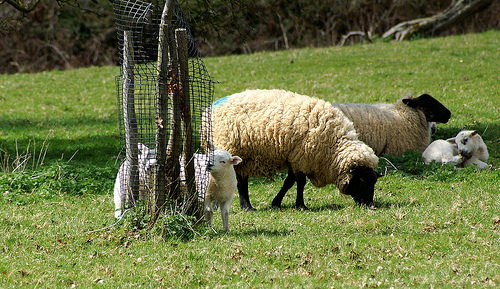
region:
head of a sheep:
[336, 128, 393, 212]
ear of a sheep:
[346, 143, 398, 181]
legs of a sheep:
[232, 172, 319, 207]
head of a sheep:
[193, 143, 243, 173]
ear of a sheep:
[232, 143, 249, 175]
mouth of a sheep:
[346, 182, 390, 220]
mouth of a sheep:
[192, 161, 227, 178]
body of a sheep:
[190, 73, 352, 184]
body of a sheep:
[336, 89, 431, 147]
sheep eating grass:
[206, 63, 438, 199]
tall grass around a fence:
[120, 190, 202, 233]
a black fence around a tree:
[109, 11, 225, 234]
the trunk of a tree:
[360, 10, 497, 34]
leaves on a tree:
[26, 0, 441, 56]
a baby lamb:
[199, 143, 252, 244]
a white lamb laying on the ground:
[418, 117, 485, 158]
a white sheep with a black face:
[224, 97, 393, 202]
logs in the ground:
[148, 16, 200, 201]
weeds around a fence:
[119, 198, 201, 233]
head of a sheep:
[335, 143, 403, 211]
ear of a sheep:
[363, 158, 390, 188]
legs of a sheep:
[230, 159, 321, 213]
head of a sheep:
[412, 79, 456, 127]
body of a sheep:
[195, 82, 330, 183]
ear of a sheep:
[403, 79, 427, 111]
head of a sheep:
[189, 138, 251, 183]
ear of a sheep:
[226, 153, 243, 164]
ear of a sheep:
[193, 132, 220, 152]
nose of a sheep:
[199, 151, 219, 176]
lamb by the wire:
[192, 137, 245, 231]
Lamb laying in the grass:
[412, 122, 487, 180]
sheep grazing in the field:
[220, 84, 377, 216]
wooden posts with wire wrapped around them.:
[128, 22, 205, 223]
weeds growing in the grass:
[9, 126, 74, 201]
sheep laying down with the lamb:
[373, 88, 496, 190]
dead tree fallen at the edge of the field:
[376, 6, 491, 36]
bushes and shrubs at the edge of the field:
[207, 7, 307, 49]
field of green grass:
[309, 50, 447, 80]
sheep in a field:
[221, 68, 498, 229]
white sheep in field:
[419, 126, 494, 173]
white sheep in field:
[332, 90, 454, 158]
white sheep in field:
[203, 86, 383, 213]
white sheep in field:
[179, 143, 244, 231]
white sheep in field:
[114, 139, 164, 218]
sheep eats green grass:
[207, 88, 383, 216]